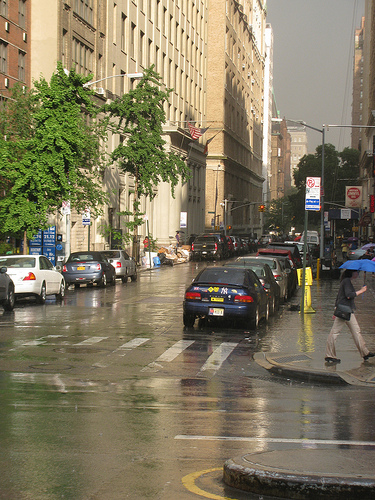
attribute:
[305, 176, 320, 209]
sign — red, white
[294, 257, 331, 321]
box — yellow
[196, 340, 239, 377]
line — white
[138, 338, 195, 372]
line — white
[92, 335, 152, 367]
line — white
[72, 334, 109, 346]
line — white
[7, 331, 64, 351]
line — white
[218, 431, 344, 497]
median — raised, cement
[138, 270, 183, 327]
street — wet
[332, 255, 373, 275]
umbrella — blue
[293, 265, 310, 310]
box — yellow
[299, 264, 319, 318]
sign — yellow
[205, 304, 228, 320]
license plate — rear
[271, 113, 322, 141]
street light — gray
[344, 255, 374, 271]
umbrella — blue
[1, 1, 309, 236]
buildings — tall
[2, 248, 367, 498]
pavement — wet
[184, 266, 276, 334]
car — blue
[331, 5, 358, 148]
wires — electric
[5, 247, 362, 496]
street — wet